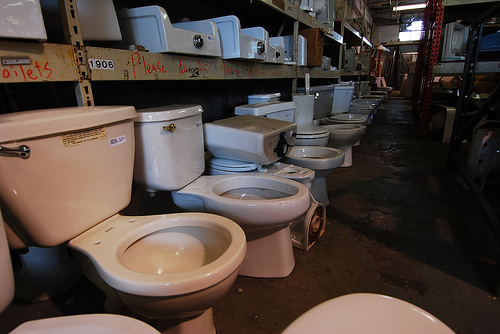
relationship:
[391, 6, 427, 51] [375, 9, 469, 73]
window on wall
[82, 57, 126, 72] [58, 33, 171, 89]
numbers on shelf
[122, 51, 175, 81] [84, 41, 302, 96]
word on shelf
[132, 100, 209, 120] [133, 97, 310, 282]
lid on toilet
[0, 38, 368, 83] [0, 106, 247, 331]
shelf above toilet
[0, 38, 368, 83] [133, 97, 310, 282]
shelf above toilet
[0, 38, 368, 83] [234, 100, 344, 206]
shelf above toilet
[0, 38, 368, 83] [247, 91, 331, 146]
shelf above toilet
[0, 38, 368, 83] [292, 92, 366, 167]
shelf above toilet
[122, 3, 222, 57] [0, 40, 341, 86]
toilet part stored on shelf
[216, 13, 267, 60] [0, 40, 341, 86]
toilet part stored on shelf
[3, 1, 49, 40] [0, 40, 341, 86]
toilet part stored on shelf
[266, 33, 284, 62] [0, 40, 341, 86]
toilet part stored on shelf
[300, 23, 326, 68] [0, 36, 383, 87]
box on shelf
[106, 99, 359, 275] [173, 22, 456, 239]
toilet in warehouse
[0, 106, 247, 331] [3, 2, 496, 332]
toilet in warehouse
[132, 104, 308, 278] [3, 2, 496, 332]
toilet in warehouse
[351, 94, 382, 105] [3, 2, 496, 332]
toilet in warehouse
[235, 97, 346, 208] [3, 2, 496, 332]
toilet in warehouse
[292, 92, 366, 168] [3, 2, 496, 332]
toilet in warehouse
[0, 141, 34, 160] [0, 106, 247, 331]
handle on toilet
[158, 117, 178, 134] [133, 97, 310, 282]
handle on toilet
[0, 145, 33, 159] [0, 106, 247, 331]
handle on toilet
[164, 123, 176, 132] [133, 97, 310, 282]
handle on toilet